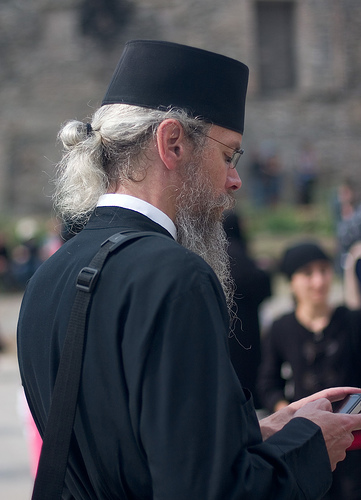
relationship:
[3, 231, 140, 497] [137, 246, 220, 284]
strap over shoulder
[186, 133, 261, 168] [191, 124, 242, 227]
glasses on face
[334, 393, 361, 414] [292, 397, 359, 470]
cell phone in hand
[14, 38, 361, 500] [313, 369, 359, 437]
man holding phone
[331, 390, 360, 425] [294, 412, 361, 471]
cell phone in hand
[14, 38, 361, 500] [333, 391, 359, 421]
man reading device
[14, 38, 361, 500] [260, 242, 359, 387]
man walking toward man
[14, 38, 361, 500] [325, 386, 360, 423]
man looks at phone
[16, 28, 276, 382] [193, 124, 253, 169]
man wears glasses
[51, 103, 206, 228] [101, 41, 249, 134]
hair under cap